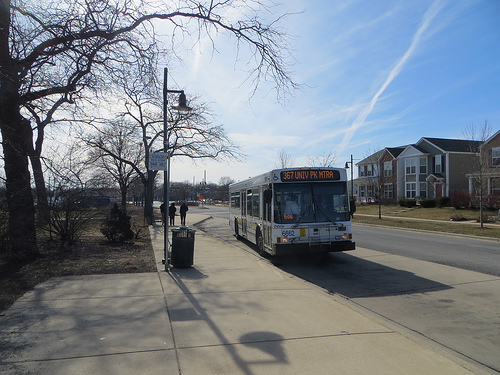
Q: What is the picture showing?
A: It is showing a sidewalk.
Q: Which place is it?
A: It is a sidewalk.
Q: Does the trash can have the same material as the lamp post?
A: Yes, both the trash can and the lamp post are made of metal.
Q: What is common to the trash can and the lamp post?
A: The material, both the trash can and the lamp post are metallic.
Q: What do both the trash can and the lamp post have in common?
A: The material, both the trash can and the lamp post are metallic.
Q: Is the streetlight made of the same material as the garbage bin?
A: Yes, both the streetlight and the garbage bin are made of metal.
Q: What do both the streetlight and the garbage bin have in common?
A: The material, both the streetlight and the garbage bin are metallic.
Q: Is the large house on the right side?
A: Yes, the house is on the right of the image.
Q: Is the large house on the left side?
A: No, the house is on the right of the image.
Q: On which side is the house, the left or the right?
A: The house is on the right of the image.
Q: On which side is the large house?
A: The house is on the right of the image.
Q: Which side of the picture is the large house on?
A: The house is on the right of the image.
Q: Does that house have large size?
A: Yes, the house is large.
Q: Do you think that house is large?
A: Yes, the house is large.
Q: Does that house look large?
A: Yes, the house is large.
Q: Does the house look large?
A: Yes, the house is large.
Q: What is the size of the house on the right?
A: The house is large.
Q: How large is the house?
A: The house is large.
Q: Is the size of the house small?
A: No, the house is large.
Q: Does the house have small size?
A: No, the house is large.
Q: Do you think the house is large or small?
A: The house is large.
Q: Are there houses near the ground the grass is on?
A: Yes, there is a house near the ground.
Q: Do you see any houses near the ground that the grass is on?
A: Yes, there is a house near the ground.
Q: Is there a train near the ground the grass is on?
A: No, there is a house near the ground.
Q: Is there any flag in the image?
A: No, there are no flags.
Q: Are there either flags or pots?
A: No, there are no flags or pots.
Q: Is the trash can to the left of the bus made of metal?
A: Yes, the trashcan is made of metal.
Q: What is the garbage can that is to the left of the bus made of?
A: The garbage bin is made of metal.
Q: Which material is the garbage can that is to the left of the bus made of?
A: The garbage bin is made of metal.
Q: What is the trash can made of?
A: The garbage bin is made of metal.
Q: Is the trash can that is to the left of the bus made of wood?
A: No, the trash can is made of metal.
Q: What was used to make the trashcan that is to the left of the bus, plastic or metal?
A: The trashcan is made of metal.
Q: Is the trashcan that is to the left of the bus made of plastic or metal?
A: The trashcan is made of metal.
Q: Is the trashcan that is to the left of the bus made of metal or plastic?
A: The trashcan is made of metal.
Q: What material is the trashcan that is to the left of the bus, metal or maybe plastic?
A: The trashcan is made of metal.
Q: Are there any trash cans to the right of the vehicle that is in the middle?
A: No, the trash can is to the left of the bus.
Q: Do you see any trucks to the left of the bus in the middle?
A: No, there is a trash can to the left of the bus.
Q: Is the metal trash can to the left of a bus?
A: Yes, the trash can is to the left of a bus.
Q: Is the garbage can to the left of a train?
A: No, the garbage can is to the left of a bus.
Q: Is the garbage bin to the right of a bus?
A: No, the garbage bin is to the left of a bus.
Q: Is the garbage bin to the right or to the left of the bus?
A: The garbage bin is to the left of the bus.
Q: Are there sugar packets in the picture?
A: No, there are no sugar packets.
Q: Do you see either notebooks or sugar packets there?
A: No, there are no sugar packets or notebooks.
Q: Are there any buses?
A: Yes, there is a bus.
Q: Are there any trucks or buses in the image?
A: Yes, there is a bus.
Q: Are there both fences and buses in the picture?
A: No, there is a bus but no fences.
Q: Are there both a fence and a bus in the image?
A: No, there is a bus but no fences.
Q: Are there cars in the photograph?
A: No, there are no cars.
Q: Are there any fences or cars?
A: No, there are no cars or fences.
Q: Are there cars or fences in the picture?
A: No, there are no cars or fences.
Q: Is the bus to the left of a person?
A: No, the bus is to the right of a person.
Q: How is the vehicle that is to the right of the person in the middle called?
A: The vehicle is a bus.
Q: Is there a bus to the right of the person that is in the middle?
A: Yes, there is a bus to the right of the person.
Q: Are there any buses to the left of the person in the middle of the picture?
A: No, the bus is to the right of the person.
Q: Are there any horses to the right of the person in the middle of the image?
A: No, there is a bus to the right of the person.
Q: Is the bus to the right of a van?
A: No, the bus is to the right of a person.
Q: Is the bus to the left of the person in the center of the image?
A: No, the bus is to the right of the person.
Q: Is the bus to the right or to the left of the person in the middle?
A: The bus is to the right of the person.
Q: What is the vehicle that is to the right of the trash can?
A: The vehicle is a bus.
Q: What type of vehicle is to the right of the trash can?
A: The vehicle is a bus.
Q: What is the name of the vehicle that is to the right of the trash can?
A: The vehicle is a bus.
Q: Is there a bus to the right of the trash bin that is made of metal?
A: Yes, there is a bus to the right of the trashcan.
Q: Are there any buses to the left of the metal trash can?
A: No, the bus is to the right of the trash can.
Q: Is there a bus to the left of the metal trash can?
A: No, the bus is to the right of the trash can.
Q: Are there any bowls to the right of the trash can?
A: No, there is a bus to the right of the trash can.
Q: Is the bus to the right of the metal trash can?
A: Yes, the bus is to the right of the garbage can.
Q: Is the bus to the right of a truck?
A: No, the bus is to the right of the garbage can.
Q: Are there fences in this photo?
A: No, there are no fences.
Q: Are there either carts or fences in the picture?
A: No, there are no fences or carts.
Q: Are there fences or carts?
A: No, there are no fences or carts.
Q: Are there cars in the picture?
A: No, there are no cars.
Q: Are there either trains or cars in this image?
A: No, there are no cars or trains.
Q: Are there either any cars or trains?
A: No, there are no cars or trains.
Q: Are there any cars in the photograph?
A: No, there are no cars.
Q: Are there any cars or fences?
A: No, there are no cars or fences.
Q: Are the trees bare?
A: Yes, the trees are bare.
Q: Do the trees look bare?
A: Yes, the trees are bare.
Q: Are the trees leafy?
A: No, the trees are bare.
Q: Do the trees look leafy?
A: No, the trees are bare.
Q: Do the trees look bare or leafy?
A: The trees are bare.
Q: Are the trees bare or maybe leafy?
A: The trees are bare.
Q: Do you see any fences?
A: No, there are no fences.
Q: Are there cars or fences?
A: No, there are no fences or cars.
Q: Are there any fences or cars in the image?
A: No, there are no fences or cars.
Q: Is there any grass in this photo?
A: Yes, there is grass.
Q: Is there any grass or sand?
A: Yes, there is grass.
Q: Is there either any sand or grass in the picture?
A: Yes, there is grass.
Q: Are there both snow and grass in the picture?
A: No, there is grass but no snow.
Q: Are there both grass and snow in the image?
A: No, there is grass but no snow.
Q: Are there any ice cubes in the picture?
A: No, there are no ice cubes.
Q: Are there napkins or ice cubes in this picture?
A: No, there are no ice cubes or napkins.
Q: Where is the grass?
A: The grass is on the ground.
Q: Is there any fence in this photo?
A: No, there are no fences.